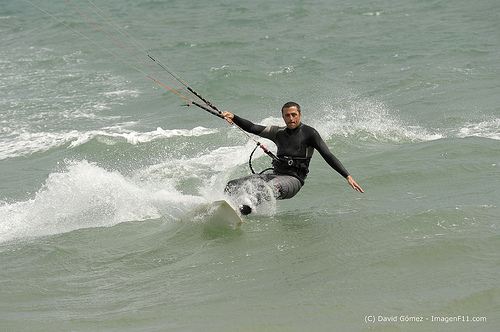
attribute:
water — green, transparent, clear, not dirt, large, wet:
[2, 1, 497, 331]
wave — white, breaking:
[0, 107, 414, 248]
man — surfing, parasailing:
[201, 91, 370, 233]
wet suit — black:
[232, 94, 350, 204]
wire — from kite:
[24, 3, 194, 106]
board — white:
[195, 193, 251, 242]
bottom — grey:
[220, 165, 308, 215]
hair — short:
[277, 103, 307, 118]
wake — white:
[15, 161, 261, 218]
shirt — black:
[230, 113, 358, 184]